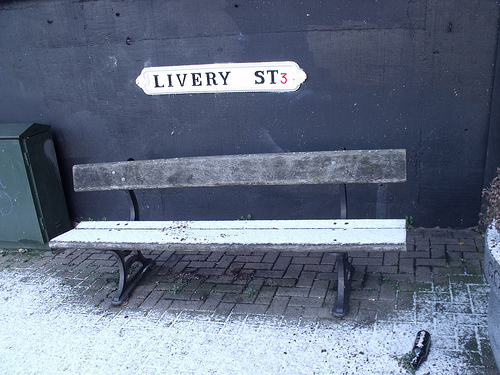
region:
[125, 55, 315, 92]
white sign with black lettering and red number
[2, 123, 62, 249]
green trash can against wall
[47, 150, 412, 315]
wooden bench in front of wall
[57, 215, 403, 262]
white seat of wooden bench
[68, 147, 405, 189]
backrest of wooden bench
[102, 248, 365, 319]
feet of wooden bench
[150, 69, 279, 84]
black lettering on sign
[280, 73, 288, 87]
red number 3 on sign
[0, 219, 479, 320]
bricks walkway under bench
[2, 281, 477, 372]
white paint on bricks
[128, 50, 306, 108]
white sign with black letters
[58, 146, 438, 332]
a wooden bench with black legs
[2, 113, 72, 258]
a green locker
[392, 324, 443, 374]
a bottle on the ground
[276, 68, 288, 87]
a red number 3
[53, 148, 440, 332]
a lopsided bench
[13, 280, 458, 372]
snow covers some of the brick ground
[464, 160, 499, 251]
a small portion of a plant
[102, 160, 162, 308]
black metal piece that holds wood for bench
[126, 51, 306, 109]
a white sign that says Livery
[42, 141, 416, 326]
a bench on a street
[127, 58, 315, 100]
a white sign in a wall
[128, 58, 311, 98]
a rectangular sign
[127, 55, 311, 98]
sign has black letters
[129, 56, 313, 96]
a red number 3 on right side of sign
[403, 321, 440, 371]
a can on side of bench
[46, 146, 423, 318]
bench is old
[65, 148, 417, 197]
rest back is made of a plank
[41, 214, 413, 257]
sit of bench has two planks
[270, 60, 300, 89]
red number 3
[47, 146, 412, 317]
Seemingly lopsided bench seat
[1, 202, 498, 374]
Scene lightly sprinkled with snow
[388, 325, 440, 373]
Abandoned beer bottle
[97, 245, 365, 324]
Iron legs on the bench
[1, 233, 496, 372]
Old style brick sidewalk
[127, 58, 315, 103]
Street sign on the wall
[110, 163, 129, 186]
Large metal screws that hold the bench together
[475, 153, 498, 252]
Corner of a plant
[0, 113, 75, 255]
Newspaper storage bin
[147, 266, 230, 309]
Trash on the ground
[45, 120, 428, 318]
A wooden bench next to a wall.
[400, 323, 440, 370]
A glass bottle on the ground.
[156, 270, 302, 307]
Bricks on the ground.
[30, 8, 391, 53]
The wall is grey.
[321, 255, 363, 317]
The metal part of the bench.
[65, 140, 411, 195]
The backboard on the bench.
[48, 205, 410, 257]
The seat of the bench.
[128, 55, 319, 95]
The sign is white with black and red text.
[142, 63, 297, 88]
The sign says Livery St 3.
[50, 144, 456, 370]
A glass bottle next to a bench.